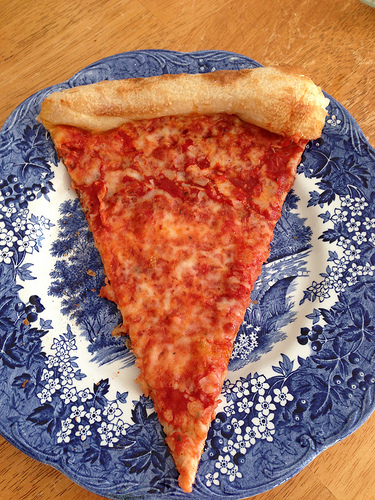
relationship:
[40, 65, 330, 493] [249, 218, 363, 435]
cheese on top of plate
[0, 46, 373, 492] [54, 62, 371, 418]
design on plate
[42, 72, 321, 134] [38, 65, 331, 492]
crust on slice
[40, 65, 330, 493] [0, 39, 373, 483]
cheese on plate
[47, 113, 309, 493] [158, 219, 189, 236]
sauce under cheese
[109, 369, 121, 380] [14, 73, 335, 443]
stain on plate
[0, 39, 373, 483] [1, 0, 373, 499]
plate on table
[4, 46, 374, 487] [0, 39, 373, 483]
design on plate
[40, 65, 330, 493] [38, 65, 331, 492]
cheese cut into a slice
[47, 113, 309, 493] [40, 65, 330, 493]
sauce on cheese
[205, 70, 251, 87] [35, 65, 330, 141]
spot on crust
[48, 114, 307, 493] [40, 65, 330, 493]
cheese on cheese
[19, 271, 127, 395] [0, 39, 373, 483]
crumbs on plate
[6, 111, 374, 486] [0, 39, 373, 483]
flower design on plate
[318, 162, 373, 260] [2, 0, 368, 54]
plate on table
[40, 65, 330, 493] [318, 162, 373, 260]
cheese on plate